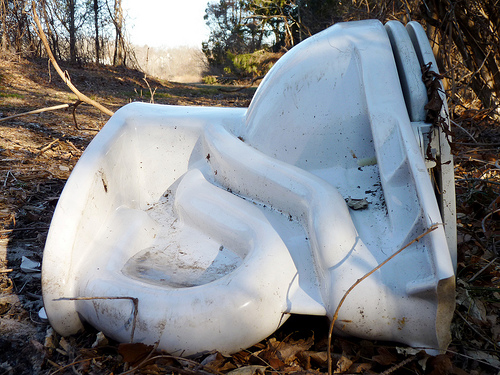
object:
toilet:
[36, 14, 466, 363]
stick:
[24, 20, 101, 121]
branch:
[45, 287, 179, 374]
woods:
[3, 1, 251, 93]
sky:
[130, 4, 202, 39]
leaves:
[269, 337, 373, 374]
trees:
[200, 0, 299, 83]